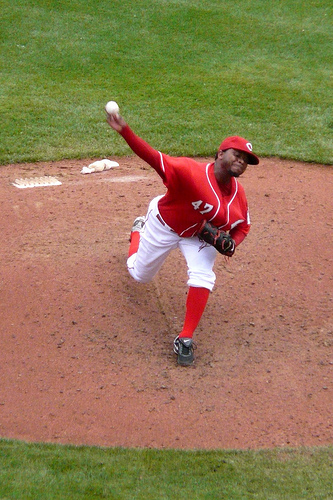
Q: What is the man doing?
A: Pitching.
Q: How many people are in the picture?
A: One.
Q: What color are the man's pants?
A: White.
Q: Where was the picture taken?
A: A baseball field.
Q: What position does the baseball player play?
A: Pitcher.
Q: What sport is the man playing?
A: Baseball.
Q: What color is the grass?
A: Green.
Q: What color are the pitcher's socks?
A: Red".